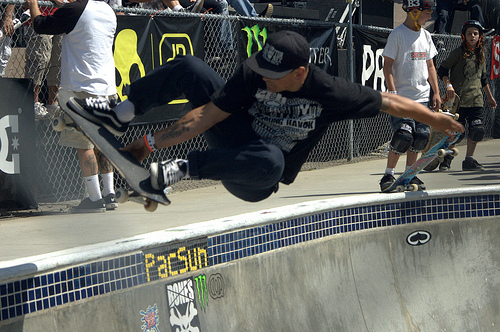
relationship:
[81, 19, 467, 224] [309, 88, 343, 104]
man wearing black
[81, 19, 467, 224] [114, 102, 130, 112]
man wearing white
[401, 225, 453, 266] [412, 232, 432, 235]
spade with background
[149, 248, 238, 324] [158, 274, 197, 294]
monster advertisement along side fence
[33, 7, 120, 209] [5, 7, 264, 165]
guy looking at spectators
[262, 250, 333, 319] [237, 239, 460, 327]
part of a surface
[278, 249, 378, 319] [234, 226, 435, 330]
part of a surface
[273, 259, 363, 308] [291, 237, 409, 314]
part of a surface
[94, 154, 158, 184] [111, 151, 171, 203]
part of a board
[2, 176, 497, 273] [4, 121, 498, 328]
edge of a surface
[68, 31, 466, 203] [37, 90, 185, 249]
man on h skateboard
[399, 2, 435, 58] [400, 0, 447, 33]
straps to a helmet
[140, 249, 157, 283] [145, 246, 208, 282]
letter on letter